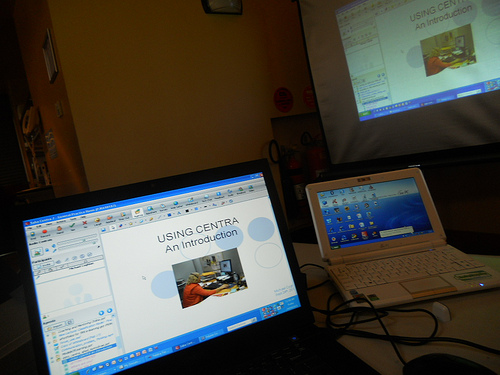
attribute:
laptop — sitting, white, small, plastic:
[302, 163, 499, 306]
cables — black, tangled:
[317, 283, 480, 354]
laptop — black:
[7, 154, 382, 375]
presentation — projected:
[333, 1, 500, 118]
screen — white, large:
[294, 2, 498, 172]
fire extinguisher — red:
[267, 128, 318, 221]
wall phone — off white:
[15, 103, 48, 142]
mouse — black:
[395, 345, 497, 373]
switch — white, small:
[50, 97, 67, 119]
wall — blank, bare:
[9, 1, 96, 196]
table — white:
[3, 235, 499, 375]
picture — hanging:
[38, 27, 63, 88]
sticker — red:
[269, 84, 300, 115]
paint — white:
[35, 4, 37, 8]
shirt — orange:
[180, 282, 218, 310]